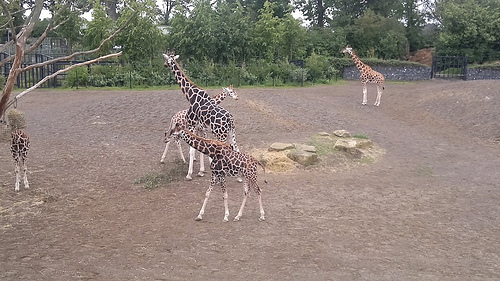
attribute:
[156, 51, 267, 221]
giraffes — brown, white, standing, tall, long, walking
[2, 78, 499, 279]
ground — brown, bare, dirt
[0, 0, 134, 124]
tree — bare, dry, leafless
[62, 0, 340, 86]
trees — green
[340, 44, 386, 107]
giraffe — long, standing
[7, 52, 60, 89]
gate — metallic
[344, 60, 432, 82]
wall — stone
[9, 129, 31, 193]
baby giraffe — standing, bowing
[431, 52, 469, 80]
fence gate — black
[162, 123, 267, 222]
giraffe — walking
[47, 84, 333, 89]
grass — green